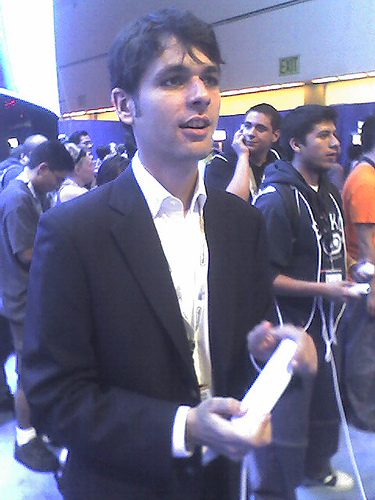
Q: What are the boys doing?
A: Playing video game.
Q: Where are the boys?
A: Gym.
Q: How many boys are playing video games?
A: Two.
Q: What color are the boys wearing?
A: Black.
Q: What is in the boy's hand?
A: Controller.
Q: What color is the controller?
A: White.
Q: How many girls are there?
A: None.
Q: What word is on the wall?
A: Exit.